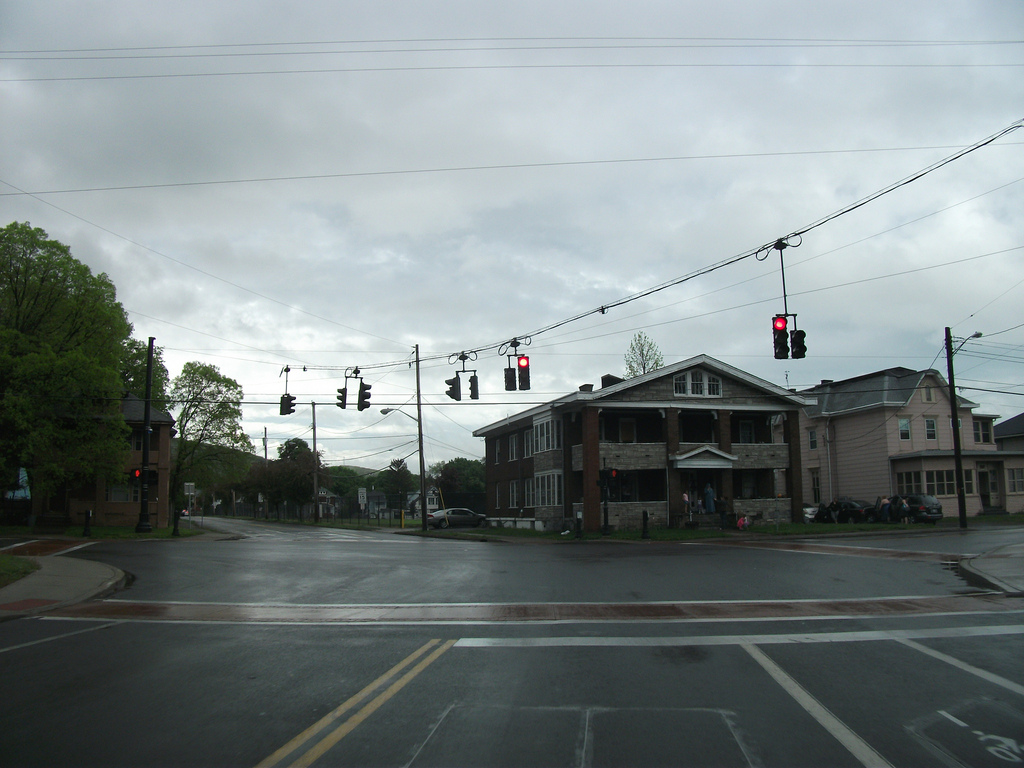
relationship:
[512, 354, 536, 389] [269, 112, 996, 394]
light hanging from wire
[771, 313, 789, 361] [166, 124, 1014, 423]
light hanging from wire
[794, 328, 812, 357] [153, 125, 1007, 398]
light hanging from wire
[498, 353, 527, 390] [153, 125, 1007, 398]
light hanging from wire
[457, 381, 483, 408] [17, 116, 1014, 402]
light hanging from wire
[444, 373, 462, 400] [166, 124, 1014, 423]
light hanging from wire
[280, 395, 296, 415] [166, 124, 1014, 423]
light hanging from wire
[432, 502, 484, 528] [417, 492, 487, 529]
car in driveway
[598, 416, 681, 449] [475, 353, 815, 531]
window on house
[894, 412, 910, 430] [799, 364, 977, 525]
window on house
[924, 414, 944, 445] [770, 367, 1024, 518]
window on house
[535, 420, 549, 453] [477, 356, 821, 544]
window on house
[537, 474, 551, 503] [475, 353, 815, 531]
window on house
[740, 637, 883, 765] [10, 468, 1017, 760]
line on street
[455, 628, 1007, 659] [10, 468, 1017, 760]
line on street